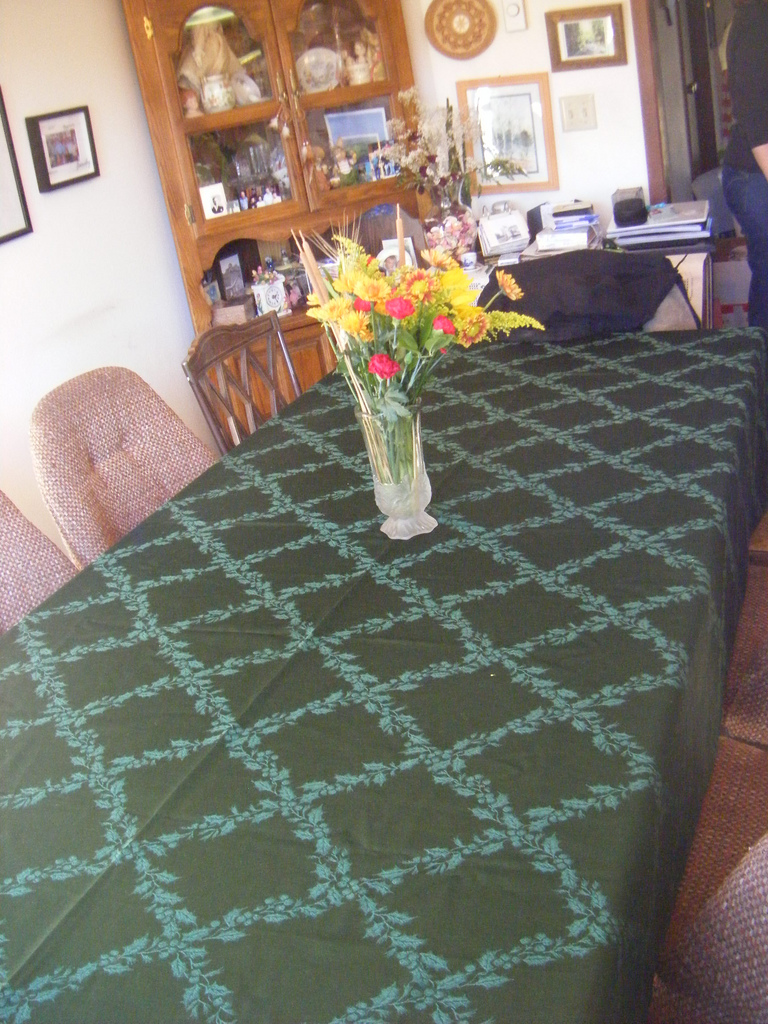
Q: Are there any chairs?
A: Yes, there is a chair.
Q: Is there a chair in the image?
A: Yes, there is a chair.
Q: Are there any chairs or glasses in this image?
A: Yes, there is a chair.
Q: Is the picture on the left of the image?
A: Yes, the picture is on the left of the image.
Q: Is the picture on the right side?
A: No, the picture is on the left of the image.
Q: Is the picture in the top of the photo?
A: Yes, the picture is in the top of the image.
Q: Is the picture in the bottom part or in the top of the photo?
A: The picture is in the top of the image.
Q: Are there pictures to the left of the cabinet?
A: Yes, there is a picture to the left of the cabinet.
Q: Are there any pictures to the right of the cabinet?
A: No, the picture is to the left of the cabinet.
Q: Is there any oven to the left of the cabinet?
A: No, there is a picture to the left of the cabinet.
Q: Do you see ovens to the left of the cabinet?
A: No, there is a picture to the left of the cabinet.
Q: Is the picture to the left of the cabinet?
A: Yes, the picture is to the left of the cabinet.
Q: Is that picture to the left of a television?
A: No, the picture is to the left of the cabinet.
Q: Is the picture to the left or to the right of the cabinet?
A: The picture is to the left of the cabinet.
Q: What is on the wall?
A: The picture is on the wall.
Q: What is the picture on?
A: The picture is on the wall.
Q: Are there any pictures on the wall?
A: Yes, there is a picture on the wall.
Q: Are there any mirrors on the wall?
A: No, there is a picture on the wall.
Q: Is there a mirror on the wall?
A: No, there is a picture on the wall.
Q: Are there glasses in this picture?
A: No, there are no glasses.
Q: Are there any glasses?
A: No, there are no glasses.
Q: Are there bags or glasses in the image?
A: No, there are no glasses or bags.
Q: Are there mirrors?
A: No, there are no mirrors.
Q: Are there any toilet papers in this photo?
A: No, there are no toilet papers.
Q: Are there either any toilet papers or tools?
A: No, there are no toilet papers or tools.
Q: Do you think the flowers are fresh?
A: Yes, the flowers are fresh.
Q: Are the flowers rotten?
A: No, the flowers are fresh.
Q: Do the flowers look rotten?
A: No, the flowers are fresh.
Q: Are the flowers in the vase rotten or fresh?
A: The flowers are fresh.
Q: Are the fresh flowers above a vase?
A: Yes, the flowers are above a vase.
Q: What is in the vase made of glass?
A: The flowers are in the vase.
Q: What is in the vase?
A: The flowers are in the vase.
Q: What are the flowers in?
A: The flowers are in the vase.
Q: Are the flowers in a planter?
A: No, the flowers are in the vase.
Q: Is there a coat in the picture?
A: Yes, there is a coat.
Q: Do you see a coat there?
A: Yes, there is a coat.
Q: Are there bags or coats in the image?
A: Yes, there is a coat.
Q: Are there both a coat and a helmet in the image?
A: No, there is a coat but no helmets.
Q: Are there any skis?
A: No, there are no skis.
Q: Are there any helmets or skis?
A: No, there are no skis or helmets.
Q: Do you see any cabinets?
A: Yes, there is a cabinet.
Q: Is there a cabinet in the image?
A: Yes, there is a cabinet.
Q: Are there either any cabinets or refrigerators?
A: Yes, there is a cabinet.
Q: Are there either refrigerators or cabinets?
A: Yes, there is a cabinet.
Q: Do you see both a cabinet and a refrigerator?
A: No, there is a cabinet but no refrigerators.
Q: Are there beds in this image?
A: No, there are no beds.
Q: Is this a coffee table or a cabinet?
A: This is a cabinet.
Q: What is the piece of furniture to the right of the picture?
A: The piece of furniture is a cabinet.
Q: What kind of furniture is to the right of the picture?
A: The piece of furniture is a cabinet.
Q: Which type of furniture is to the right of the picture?
A: The piece of furniture is a cabinet.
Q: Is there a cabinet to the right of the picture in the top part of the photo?
A: Yes, there is a cabinet to the right of the picture.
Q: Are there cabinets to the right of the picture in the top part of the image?
A: Yes, there is a cabinet to the right of the picture.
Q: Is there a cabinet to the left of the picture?
A: No, the cabinet is to the right of the picture.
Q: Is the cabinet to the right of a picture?
A: Yes, the cabinet is to the right of a picture.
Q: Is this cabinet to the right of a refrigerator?
A: No, the cabinet is to the right of a picture.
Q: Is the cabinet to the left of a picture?
A: No, the cabinet is to the right of a picture.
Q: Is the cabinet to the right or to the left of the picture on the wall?
A: The cabinet is to the right of the picture.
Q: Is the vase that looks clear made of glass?
A: Yes, the vase is made of glass.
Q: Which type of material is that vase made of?
A: The vase is made of glass.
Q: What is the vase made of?
A: The vase is made of glass.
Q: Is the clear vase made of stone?
A: No, the vase is made of glass.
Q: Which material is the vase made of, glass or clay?
A: The vase is made of glass.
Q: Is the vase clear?
A: Yes, the vase is clear.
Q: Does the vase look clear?
A: Yes, the vase is clear.